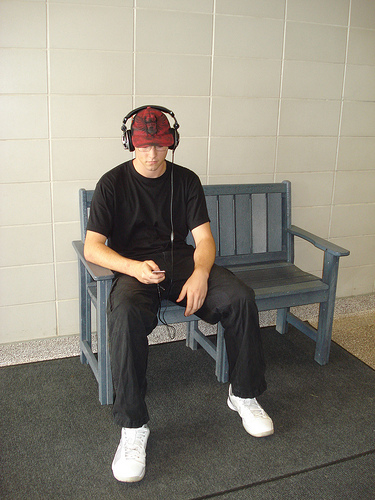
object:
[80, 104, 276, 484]
man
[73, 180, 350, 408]
bench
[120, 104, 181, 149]
headphones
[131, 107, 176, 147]
hat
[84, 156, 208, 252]
shirt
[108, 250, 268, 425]
pants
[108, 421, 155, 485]
shoe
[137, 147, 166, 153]
glasses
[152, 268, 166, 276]
ipod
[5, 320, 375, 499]
rug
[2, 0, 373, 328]
wall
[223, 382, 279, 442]
shoe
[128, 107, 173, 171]
head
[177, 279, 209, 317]
hand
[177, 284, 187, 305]
thumb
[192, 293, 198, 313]
finger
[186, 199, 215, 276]
arm